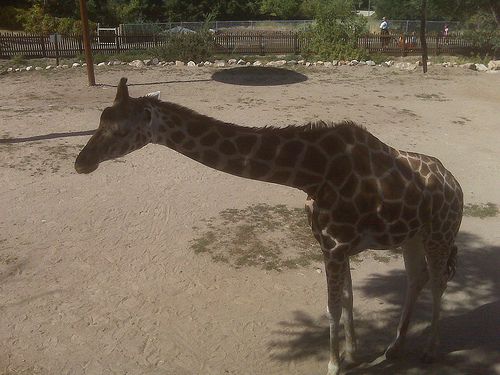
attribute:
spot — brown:
[200, 130, 220, 145]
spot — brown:
[234, 132, 257, 155]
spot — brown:
[324, 153, 351, 188]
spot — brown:
[404, 180, 421, 208]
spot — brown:
[440, 220, 453, 233]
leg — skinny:
[317, 239, 342, 373]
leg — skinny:
[337, 240, 359, 368]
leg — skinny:
[420, 219, 447, 369]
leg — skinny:
[377, 236, 437, 361]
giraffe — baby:
[75, 72, 465, 373]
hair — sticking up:
[254, 126, 421, 146]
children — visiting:
[441, 23, 451, 40]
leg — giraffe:
[418, 238, 452, 368]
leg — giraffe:
[382, 232, 429, 362]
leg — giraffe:
[320, 244, 345, 374]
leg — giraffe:
[335, 255, 361, 368]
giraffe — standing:
[46, 39, 475, 374]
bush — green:
[282, 18, 379, 53]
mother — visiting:
[354, 23, 414, 50]